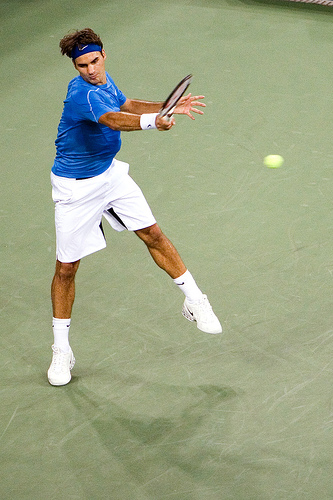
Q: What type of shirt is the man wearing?
A: Blue shirt.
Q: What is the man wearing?
A: Shorts.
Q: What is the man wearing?
A: Shorts.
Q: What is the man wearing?
A: Shorts.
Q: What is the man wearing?
A: Shoes.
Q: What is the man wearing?
A: Sports shoe.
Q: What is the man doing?
A: Swinging.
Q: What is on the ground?
A: Person's leg.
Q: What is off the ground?
A: Person's leg.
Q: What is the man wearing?
A: White shorts.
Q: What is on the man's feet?
A: White socks.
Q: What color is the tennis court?
A: Green.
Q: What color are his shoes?
A: White.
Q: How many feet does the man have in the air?
A: One.